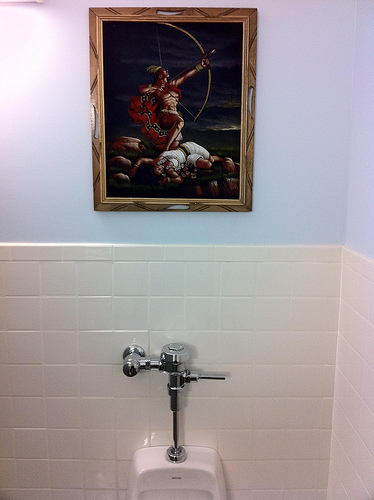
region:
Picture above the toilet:
[82, 5, 282, 208]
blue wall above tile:
[283, 129, 338, 236]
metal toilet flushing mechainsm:
[110, 334, 221, 462]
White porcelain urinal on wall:
[126, 451, 240, 493]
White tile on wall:
[203, 281, 324, 367]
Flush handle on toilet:
[191, 367, 233, 390]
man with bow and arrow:
[130, 56, 194, 155]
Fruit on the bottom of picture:
[118, 150, 240, 190]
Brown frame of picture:
[84, 187, 259, 211]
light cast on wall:
[8, 12, 53, 91]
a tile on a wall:
[12, 427, 49, 457]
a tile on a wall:
[47, 428, 83, 460]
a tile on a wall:
[45, 456, 84, 487]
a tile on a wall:
[13, 457, 51, 486]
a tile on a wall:
[12, 395, 47, 428]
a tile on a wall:
[48, 395, 80, 431]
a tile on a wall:
[80, 394, 114, 424]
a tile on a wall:
[115, 398, 148, 430]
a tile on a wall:
[10, 297, 40, 330]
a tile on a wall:
[218, 430, 250, 458]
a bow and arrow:
[152, 19, 213, 121]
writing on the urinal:
[168, 471, 186, 482]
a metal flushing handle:
[199, 364, 230, 383]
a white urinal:
[123, 438, 229, 498]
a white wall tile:
[76, 392, 116, 429]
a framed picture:
[84, 1, 257, 215]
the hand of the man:
[192, 44, 219, 76]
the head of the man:
[140, 61, 180, 93]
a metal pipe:
[164, 389, 191, 461]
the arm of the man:
[165, 61, 204, 88]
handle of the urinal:
[197, 369, 235, 392]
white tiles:
[13, 256, 93, 297]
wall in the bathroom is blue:
[176, 219, 315, 239]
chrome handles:
[144, 348, 214, 397]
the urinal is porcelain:
[138, 463, 244, 495]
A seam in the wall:
[320, 270, 353, 449]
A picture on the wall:
[101, 27, 262, 204]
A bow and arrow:
[170, 45, 243, 125]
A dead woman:
[153, 147, 220, 190]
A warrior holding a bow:
[130, 62, 191, 165]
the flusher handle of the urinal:
[196, 370, 230, 384]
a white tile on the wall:
[108, 256, 152, 298]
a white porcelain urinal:
[122, 435, 232, 498]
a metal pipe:
[164, 397, 193, 463]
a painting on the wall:
[84, 1, 261, 221]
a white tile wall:
[1, 240, 372, 497]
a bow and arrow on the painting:
[154, 18, 221, 125]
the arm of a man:
[170, 52, 217, 92]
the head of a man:
[145, 60, 173, 86]